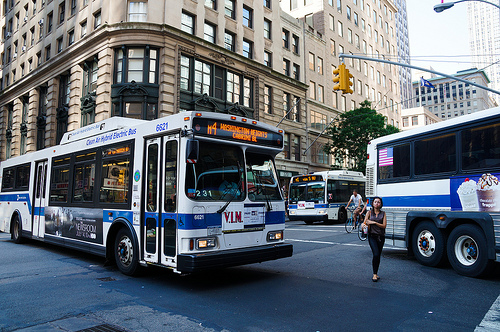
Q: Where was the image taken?
A: It was taken at the road.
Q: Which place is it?
A: It is a road.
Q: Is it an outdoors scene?
A: Yes, it is outdoors.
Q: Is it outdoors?
A: Yes, it is outdoors.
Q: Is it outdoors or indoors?
A: It is outdoors.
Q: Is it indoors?
A: No, it is outdoors.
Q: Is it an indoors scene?
A: No, it is outdoors.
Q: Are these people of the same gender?
A: No, they are both male and female.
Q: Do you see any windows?
A: Yes, there is a window.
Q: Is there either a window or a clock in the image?
A: Yes, there is a window.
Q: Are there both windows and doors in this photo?
A: Yes, there are both a window and a door.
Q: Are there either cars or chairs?
A: No, there are no cars or chairs.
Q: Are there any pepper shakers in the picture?
A: No, there are no pepper shakers.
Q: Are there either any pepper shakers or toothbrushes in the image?
A: No, there are no pepper shakers or toothbrushes.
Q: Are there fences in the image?
A: No, there are no fences.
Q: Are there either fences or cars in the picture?
A: No, there are no fences or cars.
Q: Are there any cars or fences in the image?
A: No, there are no fences or cars.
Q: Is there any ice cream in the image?
A: Yes, there is ice cream.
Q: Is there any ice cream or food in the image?
A: Yes, there is ice cream.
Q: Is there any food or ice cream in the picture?
A: Yes, there is ice cream.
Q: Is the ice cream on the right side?
A: Yes, the ice cream is on the right of the image.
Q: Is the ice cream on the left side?
A: No, the ice cream is on the right of the image.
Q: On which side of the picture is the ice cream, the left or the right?
A: The ice cream is on the right of the image.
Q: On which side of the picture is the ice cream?
A: The ice cream is on the right of the image.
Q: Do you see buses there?
A: Yes, there is a bus.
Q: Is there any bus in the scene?
A: Yes, there is a bus.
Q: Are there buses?
A: Yes, there is a bus.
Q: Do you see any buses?
A: Yes, there is a bus.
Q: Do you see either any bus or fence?
A: Yes, there is a bus.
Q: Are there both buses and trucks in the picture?
A: No, there is a bus but no trucks.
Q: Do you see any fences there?
A: No, there are no fences.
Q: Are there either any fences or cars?
A: No, there are no fences or cars.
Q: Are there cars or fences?
A: No, there are no fences or cars.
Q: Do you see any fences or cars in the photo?
A: No, there are no fences or cars.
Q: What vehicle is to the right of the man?
A: The vehicle is a bus.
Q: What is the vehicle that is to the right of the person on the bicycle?
A: The vehicle is a bus.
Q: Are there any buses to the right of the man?
A: Yes, there is a bus to the right of the man.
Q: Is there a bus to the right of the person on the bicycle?
A: Yes, there is a bus to the right of the man.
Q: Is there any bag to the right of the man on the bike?
A: No, there is a bus to the right of the man.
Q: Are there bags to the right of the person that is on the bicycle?
A: No, there is a bus to the right of the man.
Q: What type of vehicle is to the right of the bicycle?
A: The vehicle is a bus.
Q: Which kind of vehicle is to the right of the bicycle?
A: The vehicle is a bus.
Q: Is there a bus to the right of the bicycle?
A: Yes, there is a bus to the right of the bicycle.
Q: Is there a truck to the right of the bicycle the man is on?
A: No, there is a bus to the right of the bicycle.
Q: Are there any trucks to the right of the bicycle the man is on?
A: No, there is a bus to the right of the bicycle.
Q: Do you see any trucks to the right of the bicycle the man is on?
A: No, there is a bus to the right of the bicycle.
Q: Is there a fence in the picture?
A: No, there are no fences.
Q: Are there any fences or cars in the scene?
A: No, there are no fences or cars.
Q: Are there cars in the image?
A: No, there are no cars.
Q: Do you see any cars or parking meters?
A: No, there are no cars or parking meters.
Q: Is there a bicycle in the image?
A: Yes, there is a bicycle.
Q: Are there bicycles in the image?
A: Yes, there is a bicycle.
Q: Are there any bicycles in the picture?
A: Yes, there is a bicycle.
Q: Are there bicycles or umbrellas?
A: Yes, there is a bicycle.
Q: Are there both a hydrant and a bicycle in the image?
A: No, there is a bicycle but no fire hydrants.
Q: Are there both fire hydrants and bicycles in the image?
A: No, there is a bicycle but no fire hydrants.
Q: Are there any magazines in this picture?
A: No, there are no magazines.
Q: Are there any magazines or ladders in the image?
A: No, there are no magazines or ladders.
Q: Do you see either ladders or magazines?
A: No, there are no magazines or ladders.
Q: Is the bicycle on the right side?
A: Yes, the bicycle is on the right of the image.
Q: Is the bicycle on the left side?
A: No, the bicycle is on the right of the image.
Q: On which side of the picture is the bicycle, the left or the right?
A: The bicycle is on the right of the image.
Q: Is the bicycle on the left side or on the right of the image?
A: The bicycle is on the right of the image.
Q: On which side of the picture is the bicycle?
A: The bicycle is on the right of the image.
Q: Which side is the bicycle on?
A: The bicycle is on the right of the image.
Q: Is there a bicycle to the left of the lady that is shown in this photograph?
A: Yes, there is a bicycle to the left of the lady.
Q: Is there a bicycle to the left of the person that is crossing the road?
A: Yes, there is a bicycle to the left of the lady.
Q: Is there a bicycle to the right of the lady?
A: No, the bicycle is to the left of the lady.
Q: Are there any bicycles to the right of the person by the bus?
A: No, the bicycle is to the left of the lady.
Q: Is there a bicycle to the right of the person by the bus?
A: No, the bicycle is to the left of the lady.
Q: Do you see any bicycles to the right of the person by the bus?
A: No, the bicycle is to the left of the lady.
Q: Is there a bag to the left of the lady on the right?
A: No, there is a bicycle to the left of the lady.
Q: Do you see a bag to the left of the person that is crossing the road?
A: No, there is a bicycle to the left of the lady.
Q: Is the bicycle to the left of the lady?
A: Yes, the bicycle is to the left of the lady.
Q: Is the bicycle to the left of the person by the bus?
A: Yes, the bicycle is to the left of the lady.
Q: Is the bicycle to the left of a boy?
A: No, the bicycle is to the left of the lady.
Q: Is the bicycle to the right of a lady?
A: No, the bicycle is to the left of a lady.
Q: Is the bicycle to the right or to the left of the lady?
A: The bicycle is to the left of the lady.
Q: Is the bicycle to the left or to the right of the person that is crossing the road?
A: The bicycle is to the left of the lady.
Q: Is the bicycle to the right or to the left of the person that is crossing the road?
A: The bicycle is to the left of the lady.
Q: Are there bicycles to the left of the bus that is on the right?
A: Yes, there is a bicycle to the left of the bus.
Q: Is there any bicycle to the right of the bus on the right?
A: No, the bicycle is to the left of the bus.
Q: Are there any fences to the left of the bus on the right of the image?
A: No, there is a bicycle to the left of the bus.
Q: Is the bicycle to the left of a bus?
A: Yes, the bicycle is to the left of a bus.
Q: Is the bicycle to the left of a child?
A: No, the bicycle is to the left of a bus.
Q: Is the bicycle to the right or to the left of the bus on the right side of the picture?
A: The bicycle is to the left of the bus.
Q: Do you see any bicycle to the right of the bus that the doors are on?
A: Yes, there is a bicycle to the right of the bus.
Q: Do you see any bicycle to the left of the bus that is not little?
A: No, the bicycle is to the right of the bus.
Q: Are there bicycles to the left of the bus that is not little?
A: No, the bicycle is to the right of the bus.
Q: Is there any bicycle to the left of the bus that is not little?
A: No, the bicycle is to the right of the bus.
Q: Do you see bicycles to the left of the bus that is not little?
A: No, the bicycle is to the right of the bus.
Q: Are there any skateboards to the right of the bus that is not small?
A: No, there is a bicycle to the right of the bus.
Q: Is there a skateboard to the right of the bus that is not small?
A: No, there is a bicycle to the right of the bus.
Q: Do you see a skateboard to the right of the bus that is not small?
A: No, there is a bicycle to the right of the bus.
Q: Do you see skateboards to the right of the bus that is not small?
A: No, there is a bicycle to the right of the bus.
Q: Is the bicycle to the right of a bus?
A: Yes, the bicycle is to the right of a bus.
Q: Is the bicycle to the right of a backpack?
A: No, the bicycle is to the right of a bus.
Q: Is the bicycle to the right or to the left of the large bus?
A: The bicycle is to the right of the bus.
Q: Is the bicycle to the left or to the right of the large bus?
A: The bicycle is to the right of the bus.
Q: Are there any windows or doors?
A: Yes, there is a window.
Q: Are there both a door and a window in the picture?
A: Yes, there are both a window and a door.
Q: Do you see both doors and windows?
A: Yes, there are both a window and a door.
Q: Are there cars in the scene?
A: No, there are no cars.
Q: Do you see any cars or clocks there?
A: No, there are no cars or clocks.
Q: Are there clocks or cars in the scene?
A: No, there are no cars or clocks.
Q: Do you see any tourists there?
A: No, there are no tourists.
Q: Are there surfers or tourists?
A: No, there are no tourists or surfers.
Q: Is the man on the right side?
A: Yes, the man is on the right of the image.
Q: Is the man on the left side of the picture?
A: No, the man is on the right of the image.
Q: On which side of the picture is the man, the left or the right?
A: The man is on the right of the image.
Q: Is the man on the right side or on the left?
A: The man is on the right of the image.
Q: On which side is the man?
A: The man is on the right of the image.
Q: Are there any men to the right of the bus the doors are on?
A: Yes, there is a man to the right of the bus.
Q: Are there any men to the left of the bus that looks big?
A: No, the man is to the right of the bus.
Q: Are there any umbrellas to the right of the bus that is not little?
A: No, there is a man to the right of the bus.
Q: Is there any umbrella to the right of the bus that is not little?
A: No, there is a man to the right of the bus.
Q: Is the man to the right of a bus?
A: Yes, the man is to the right of a bus.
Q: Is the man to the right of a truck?
A: No, the man is to the right of a bus.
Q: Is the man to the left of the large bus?
A: No, the man is to the right of the bus.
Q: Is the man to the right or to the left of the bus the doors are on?
A: The man is to the right of the bus.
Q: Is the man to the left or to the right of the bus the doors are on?
A: The man is to the right of the bus.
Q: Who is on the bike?
A: The man is on the bike.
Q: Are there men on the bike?
A: Yes, there is a man on the bike.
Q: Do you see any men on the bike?
A: Yes, there is a man on the bike.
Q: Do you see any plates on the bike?
A: No, there is a man on the bike.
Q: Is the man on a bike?
A: Yes, the man is on a bike.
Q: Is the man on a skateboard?
A: No, the man is on a bike.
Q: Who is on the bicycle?
A: The man is on the bicycle.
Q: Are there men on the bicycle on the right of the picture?
A: Yes, there is a man on the bicycle.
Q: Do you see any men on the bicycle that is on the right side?
A: Yes, there is a man on the bicycle.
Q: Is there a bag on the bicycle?
A: No, there is a man on the bicycle.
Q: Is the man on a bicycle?
A: Yes, the man is on a bicycle.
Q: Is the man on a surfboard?
A: No, the man is on a bicycle.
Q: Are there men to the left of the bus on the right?
A: Yes, there is a man to the left of the bus.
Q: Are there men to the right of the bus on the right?
A: No, the man is to the left of the bus.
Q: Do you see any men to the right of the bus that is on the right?
A: No, the man is to the left of the bus.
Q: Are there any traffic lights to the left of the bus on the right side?
A: No, there is a man to the left of the bus.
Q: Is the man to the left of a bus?
A: Yes, the man is to the left of a bus.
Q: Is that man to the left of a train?
A: No, the man is to the left of a bus.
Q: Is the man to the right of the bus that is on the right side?
A: No, the man is to the left of the bus.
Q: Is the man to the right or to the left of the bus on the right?
A: The man is to the left of the bus.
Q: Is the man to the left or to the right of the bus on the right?
A: The man is to the left of the bus.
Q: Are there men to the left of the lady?
A: Yes, there is a man to the left of the lady.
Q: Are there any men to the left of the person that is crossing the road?
A: Yes, there is a man to the left of the lady.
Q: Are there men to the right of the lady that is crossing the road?
A: No, the man is to the left of the lady.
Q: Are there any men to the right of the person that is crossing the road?
A: No, the man is to the left of the lady.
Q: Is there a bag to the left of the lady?
A: No, there is a man to the left of the lady.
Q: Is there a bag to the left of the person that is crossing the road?
A: No, there is a man to the left of the lady.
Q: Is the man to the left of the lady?
A: Yes, the man is to the left of the lady.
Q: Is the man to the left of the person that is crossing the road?
A: Yes, the man is to the left of the lady.